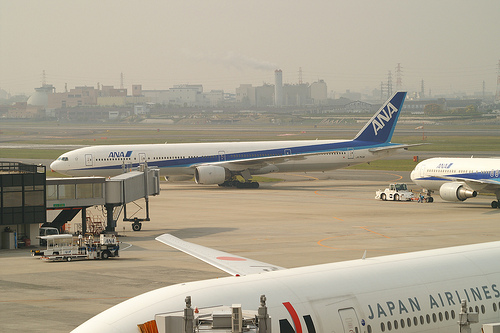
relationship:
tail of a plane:
[363, 93, 414, 147] [63, 112, 465, 179]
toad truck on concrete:
[374, 183, 416, 202] [354, 193, 455, 258]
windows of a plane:
[382, 300, 423, 330] [162, 257, 477, 330]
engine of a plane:
[432, 172, 475, 209] [384, 136, 482, 212]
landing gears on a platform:
[237, 181, 260, 188] [18, 76, 479, 213]